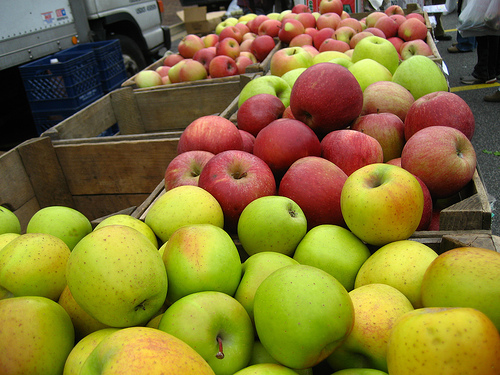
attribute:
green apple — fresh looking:
[336, 162, 429, 237]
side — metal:
[4, 2, 83, 73]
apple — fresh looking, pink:
[396, 113, 498, 201]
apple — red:
[291, 62, 368, 134]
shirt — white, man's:
[457, 0, 498, 26]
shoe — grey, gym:
[460, 70, 499, 90]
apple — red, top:
[282, 55, 389, 145]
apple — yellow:
[384, 306, 498, 373]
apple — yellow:
[420, 247, 499, 310]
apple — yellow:
[355, 238, 442, 310]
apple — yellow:
[342, 162, 424, 244]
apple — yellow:
[65, 226, 167, 327]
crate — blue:
[16, 46, 101, 113]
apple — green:
[59, 220, 171, 331]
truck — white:
[0, 2, 185, 59]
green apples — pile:
[123, 205, 326, 339]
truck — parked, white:
[13, 7, 163, 53]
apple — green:
[1, 202, 24, 237]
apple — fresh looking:
[61, 225, 174, 326]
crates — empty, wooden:
[9, 82, 239, 219]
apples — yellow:
[3, 191, 499, 371]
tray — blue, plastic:
[12, 46, 110, 111]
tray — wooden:
[0, 137, 180, 224]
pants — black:
[470, 30, 499, 83]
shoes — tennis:
[460, 72, 497, 85]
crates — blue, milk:
[56, 45, 121, 105]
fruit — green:
[257, 264, 352, 368]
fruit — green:
[64, 224, 172, 329]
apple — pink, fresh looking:
[249, 112, 323, 168]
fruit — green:
[160, 290, 252, 374]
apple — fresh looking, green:
[253, 266, 355, 373]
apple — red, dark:
[200, 149, 277, 212]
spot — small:
[208, 170, 217, 182]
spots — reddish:
[265, 273, 342, 334]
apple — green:
[162, 289, 251, 372]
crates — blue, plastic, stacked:
[19, 36, 127, 134]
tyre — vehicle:
[107, 28, 147, 78]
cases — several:
[11, 14, 485, 362]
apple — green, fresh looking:
[0, 238, 70, 298]